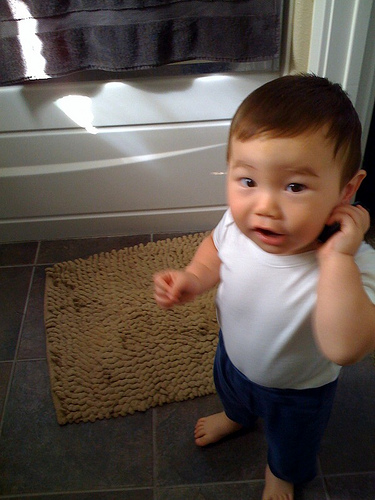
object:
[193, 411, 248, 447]
naked feet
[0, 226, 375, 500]
ground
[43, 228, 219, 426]
mat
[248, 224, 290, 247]
mouth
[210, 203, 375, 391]
shirt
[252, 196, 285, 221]
nose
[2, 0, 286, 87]
towel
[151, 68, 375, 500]
baby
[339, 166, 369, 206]
ear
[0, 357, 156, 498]
tile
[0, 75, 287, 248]
tub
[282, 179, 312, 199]
eyes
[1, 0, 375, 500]
bathroom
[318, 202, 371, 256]
hand